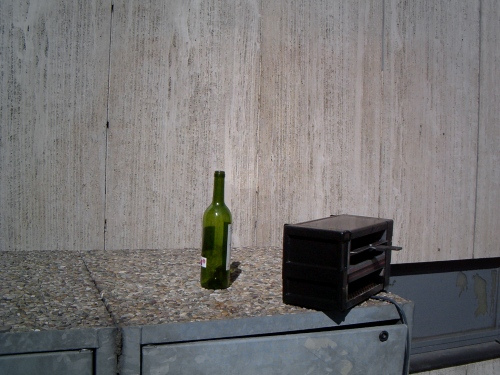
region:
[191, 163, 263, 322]
The bottle is green glass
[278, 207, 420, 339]
There is a black object on the counter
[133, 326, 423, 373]
The cabinet has a small lock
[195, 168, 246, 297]
The bottle has a white lable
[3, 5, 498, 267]
The wall is wooden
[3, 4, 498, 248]
The wall is tan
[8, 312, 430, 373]
The cabinets are grey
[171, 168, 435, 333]
The bottle is next to the black object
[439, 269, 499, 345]
The pain is chipping off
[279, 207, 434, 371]
There is a cord coming from the black object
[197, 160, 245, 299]
an empty green wine bottle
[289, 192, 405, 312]
a black, broken toaster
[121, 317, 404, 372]
some old cabinets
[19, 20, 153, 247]
a faux wooden wall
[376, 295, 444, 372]
an electrical cord for the toaster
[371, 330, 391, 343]
a keyhole for the cabinets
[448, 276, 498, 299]
splotch of worn off paint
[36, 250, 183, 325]
faux stone tops on the cabinets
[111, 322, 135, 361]
hinges for the cabinets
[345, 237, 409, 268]
a removable tray for the toaster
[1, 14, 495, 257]
wood paneling in a house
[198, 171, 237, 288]
wine bottle sitting on counter of room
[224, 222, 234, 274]
partial label on wine bottle on counter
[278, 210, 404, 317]
back of an old cd radio combination stero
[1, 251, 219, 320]
old marble looking counter top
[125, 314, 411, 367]
top of cabinet door under cabinet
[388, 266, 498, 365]
blue wood room divider with paint falling off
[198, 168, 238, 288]
The wine bottle is green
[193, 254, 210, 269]
back label of wine bottle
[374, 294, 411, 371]
electrical cord attached to the cd/radio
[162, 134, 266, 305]
green bottle on counter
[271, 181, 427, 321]
black box on table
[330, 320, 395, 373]
blue cabinet with black knob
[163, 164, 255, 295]
empty green bottle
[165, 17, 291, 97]
gray wall next to bottle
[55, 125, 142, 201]
line on the wall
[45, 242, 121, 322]
crack on the counter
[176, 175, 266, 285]
green bottle with white label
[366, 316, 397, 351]
black knob on cabinet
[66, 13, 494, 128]
lines on the wall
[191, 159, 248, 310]
a bottle of wine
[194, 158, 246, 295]
a green bottle of wine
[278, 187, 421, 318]
a black unknown box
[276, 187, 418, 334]
a black toaster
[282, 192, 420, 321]
a black toaster oven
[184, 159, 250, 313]
a tall wine bottle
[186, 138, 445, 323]
a wine bottle sitting next to a black toaster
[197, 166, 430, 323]
a green wine bottle standing next to an unknown object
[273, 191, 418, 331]
a black toaster with no food in it